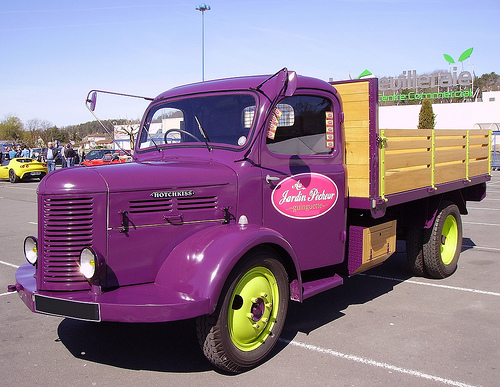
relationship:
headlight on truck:
[21, 234, 41, 264] [6, 68, 491, 375]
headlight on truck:
[78, 245, 97, 279] [6, 68, 491, 375]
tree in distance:
[1, 115, 25, 142] [0, 98, 139, 146]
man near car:
[42, 141, 56, 172] [0, 155, 46, 185]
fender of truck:
[153, 220, 301, 295] [6, 68, 491, 375]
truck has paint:
[6, 68, 491, 375] [17, 70, 349, 323]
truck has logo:
[6, 68, 491, 375] [270, 170, 340, 220]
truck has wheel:
[6, 68, 491, 375] [424, 202, 462, 279]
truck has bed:
[6, 68, 491, 375] [378, 125, 492, 197]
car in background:
[0, 155, 46, 185] [1, 114, 137, 182]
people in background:
[6, 140, 87, 169] [1, 114, 137, 182]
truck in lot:
[6, 68, 491, 375] [0, 143, 499, 385]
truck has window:
[6, 68, 491, 375] [266, 91, 335, 156]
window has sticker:
[266, 91, 335, 156] [325, 142, 334, 149]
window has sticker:
[266, 91, 335, 156] [325, 134, 333, 142]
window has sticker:
[266, 91, 335, 156] [325, 110, 335, 119]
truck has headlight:
[6, 68, 491, 375] [21, 234, 41, 264]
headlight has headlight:
[21, 234, 41, 264] [21, 234, 41, 264]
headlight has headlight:
[78, 245, 97, 279] [78, 245, 97, 279]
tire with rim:
[198, 252, 293, 376] [228, 267, 280, 351]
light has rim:
[21, 234, 41, 264] [23, 236, 30, 264]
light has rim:
[21, 234, 41, 264] [24, 260, 38, 267]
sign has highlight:
[378, 91, 474, 102] [457, 47, 473, 63]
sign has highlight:
[378, 91, 474, 102] [442, 52, 456, 66]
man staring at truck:
[42, 141, 56, 172] [6, 68, 491, 375]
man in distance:
[42, 141, 56, 172] [0, 98, 139, 146]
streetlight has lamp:
[192, 1, 211, 84] [205, 5, 211, 11]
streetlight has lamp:
[192, 1, 211, 84] [195, 5, 200, 10]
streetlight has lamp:
[192, 1, 211, 84] [201, 5, 206, 10]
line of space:
[281, 335, 477, 386] [279, 271, 496, 385]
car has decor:
[83, 154, 129, 167] [112, 155, 122, 163]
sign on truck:
[270, 170, 340, 220] [6, 68, 491, 375]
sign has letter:
[270, 170, 340, 220] [279, 191, 287, 206]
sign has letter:
[270, 170, 340, 220] [286, 196, 291, 203]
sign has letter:
[270, 170, 340, 220] [308, 188, 316, 203]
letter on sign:
[279, 191, 287, 206] [270, 170, 340, 220]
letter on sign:
[286, 196, 291, 203] [270, 170, 340, 220]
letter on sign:
[408, 90, 415, 102] [378, 91, 474, 102]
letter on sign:
[432, 91, 443, 101] [378, 91, 474, 102]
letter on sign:
[387, 94, 394, 102] [378, 91, 474, 102]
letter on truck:
[154, 193, 160, 198] [6, 68, 491, 375]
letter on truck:
[167, 192, 172, 198] [6, 68, 491, 375]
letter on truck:
[184, 190, 188, 196] [6, 68, 491, 375]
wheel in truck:
[163, 126, 200, 145] [6, 68, 491, 375]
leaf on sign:
[442, 52, 456, 66] [378, 91, 474, 102]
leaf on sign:
[457, 47, 473, 63] [378, 91, 474, 102]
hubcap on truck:
[228, 267, 280, 351] [6, 68, 491, 375]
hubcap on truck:
[439, 217, 456, 266] [6, 68, 491, 375]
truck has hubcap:
[6, 68, 491, 375] [228, 267, 280, 351]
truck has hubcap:
[6, 68, 491, 375] [439, 217, 456, 266]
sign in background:
[378, 91, 474, 102] [376, 66, 497, 130]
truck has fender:
[6, 68, 491, 375] [153, 220, 301, 295]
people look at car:
[6, 140, 87, 169] [0, 155, 46, 185]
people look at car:
[6, 140, 87, 169] [83, 154, 129, 167]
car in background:
[83, 154, 129, 167] [1, 114, 137, 182]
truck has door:
[6, 68, 491, 375] [90, 157, 241, 230]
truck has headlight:
[6, 68, 491, 375] [78, 245, 97, 279]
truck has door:
[6, 68, 491, 375] [258, 87, 346, 270]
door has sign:
[258, 87, 346, 270] [270, 170, 340, 220]